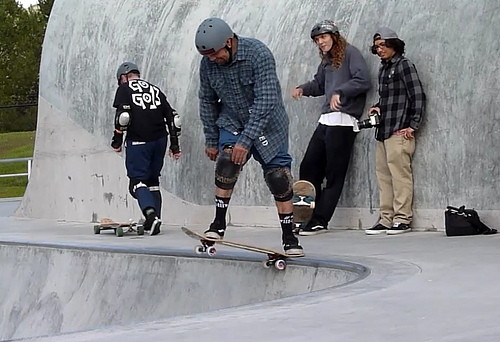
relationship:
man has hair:
[291, 18, 373, 235] [329, 30, 354, 68]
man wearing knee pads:
[194, 16, 305, 257] [212, 144, 294, 201]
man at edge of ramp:
[194, 16, 305, 257] [0, 237, 370, 340]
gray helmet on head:
[193, 13, 234, 57] [192, 16, 247, 63]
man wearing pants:
[291, 18, 373, 235] [298, 120, 363, 224]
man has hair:
[284, 17, 376, 242] [322, 24, 347, 71]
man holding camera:
[367, 27, 426, 235] [354, 113, 381, 130]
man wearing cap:
[367, 27, 426, 235] [368, 26, 401, 41]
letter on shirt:
[128, 79, 163, 110] [110, 78, 179, 155]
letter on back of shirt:
[128, 79, 163, 110] [110, 78, 179, 155]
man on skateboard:
[181, 15, 319, 263] [178, 208, 303, 279]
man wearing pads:
[194, 16, 305, 257] [212, 146, 294, 203]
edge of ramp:
[68, 227, 199, 260] [24, 222, 149, 338]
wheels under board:
[191, 243, 218, 256] [178, 224, 292, 269]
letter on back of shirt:
[128, 79, 163, 110] [109, 78, 175, 143]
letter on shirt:
[128, 79, 163, 110] [110, 77, 181, 145]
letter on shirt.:
[128, 79, 163, 110] [116, 82, 171, 134]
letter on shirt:
[128, 79, 163, 110] [300, 36, 377, 117]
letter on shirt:
[128, 79, 163, 110] [61, 52, 185, 209]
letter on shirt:
[132, 87, 147, 112] [111, 74, 176, 152]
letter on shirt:
[128, 79, 163, 110] [111, 74, 176, 152]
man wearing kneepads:
[194, 16, 305, 257] [178, 142, 292, 197]